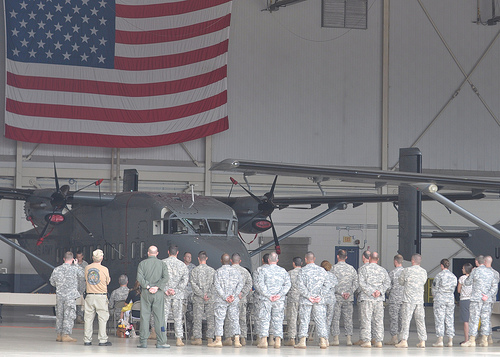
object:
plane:
[0, 144, 495, 297]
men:
[137, 244, 172, 348]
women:
[316, 260, 339, 347]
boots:
[206, 337, 243, 348]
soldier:
[395, 254, 428, 348]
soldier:
[461, 255, 498, 347]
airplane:
[0, 165, 483, 289]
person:
[82, 248, 111, 345]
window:
[164, 219, 236, 234]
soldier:
[223, 252, 253, 345]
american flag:
[4, 0, 233, 148]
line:
[49, 235, 498, 352]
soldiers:
[384, 254, 407, 346]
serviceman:
[48, 251, 86, 343]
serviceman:
[108, 274, 132, 315]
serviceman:
[328, 249, 360, 345]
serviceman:
[160, 244, 188, 346]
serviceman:
[293, 251, 331, 349]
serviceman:
[353, 250, 384, 345]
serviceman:
[395, 254, 428, 348]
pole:
[379, 1, 392, 278]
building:
[2, 2, 499, 309]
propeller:
[229, 174, 312, 254]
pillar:
[397, 147, 422, 261]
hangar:
[5, 10, 496, 321]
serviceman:
[359, 251, 392, 347]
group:
[47, 245, 496, 349]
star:
[97, 55, 106, 64]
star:
[98, 37, 107, 47]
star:
[62, 51, 71, 60]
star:
[98, 16, 108, 26]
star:
[27, 29, 37, 38]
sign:
[343, 236, 352, 242]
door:
[335, 246, 359, 270]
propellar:
[0, 154, 104, 246]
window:
[320, 0, 368, 30]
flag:
[0, 0, 230, 150]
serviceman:
[431, 258, 458, 346]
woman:
[124, 279, 142, 318]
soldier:
[189, 251, 218, 346]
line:
[49, 244, 497, 345]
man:
[207, 253, 244, 347]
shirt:
[85, 263, 111, 293]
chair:
[130, 301, 140, 324]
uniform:
[136, 256, 170, 345]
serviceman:
[253, 251, 291, 349]